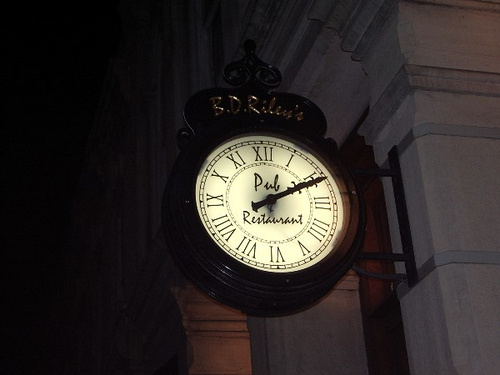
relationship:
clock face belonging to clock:
[192, 128, 347, 278] [159, 34, 370, 321]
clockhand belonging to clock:
[251, 177, 328, 213] [163, 86, 358, 303]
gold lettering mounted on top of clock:
[207, 88, 309, 124] [155, 117, 367, 315]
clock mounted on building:
[178, 126, 355, 286] [99, 4, 485, 372]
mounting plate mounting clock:
[336, 122, 422, 308] [155, 117, 367, 315]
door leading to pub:
[332, 132, 407, 373] [95, 4, 485, 372]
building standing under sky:
[31, 2, 499, 367] [1, 3, 124, 370]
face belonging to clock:
[194, 133, 349, 274] [155, 117, 367, 315]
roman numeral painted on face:
[207, 211, 237, 242] [194, 133, 349, 274]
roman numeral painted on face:
[232, 235, 261, 259] [194, 133, 349, 274]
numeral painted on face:
[270, 246, 285, 263] [194, 133, 349, 274]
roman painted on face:
[298, 240, 310, 255] [194, 133, 349, 274]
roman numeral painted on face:
[308, 219, 330, 242] [194, 133, 349, 274]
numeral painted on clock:
[270, 246, 285, 263] [145, 43, 359, 319]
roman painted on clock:
[298, 240, 310, 255] [145, 43, 359, 319]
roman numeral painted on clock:
[304, 212, 334, 242] [145, 43, 359, 319]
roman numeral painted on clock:
[312, 191, 334, 212] [145, 43, 359, 319]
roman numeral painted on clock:
[202, 191, 227, 207] [145, 43, 359, 319]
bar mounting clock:
[349, 144, 418, 288] [157, 77, 391, 289]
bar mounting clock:
[349, 264, 411, 283] [157, 77, 391, 289]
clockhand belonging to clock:
[251, 177, 328, 213] [178, 126, 355, 286]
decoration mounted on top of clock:
[208, 45, 284, 95] [122, 82, 352, 282]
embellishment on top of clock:
[222, 38, 286, 93] [163, 120, 357, 319]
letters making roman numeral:
[314, 191, 332, 211] [312, 191, 334, 212]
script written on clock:
[241, 168, 306, 226] [158, 82, 369, 319]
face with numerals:
[162, 110, 366, 285] [267, 235, 289, 269]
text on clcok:
[238, 171, 307, 226] [157, 102, 398, 336]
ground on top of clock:
[368, 162, 411, 199] [152, 10, 377, 321]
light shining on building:
[174, 286, 254, 366] [39, 33, 468, 353]